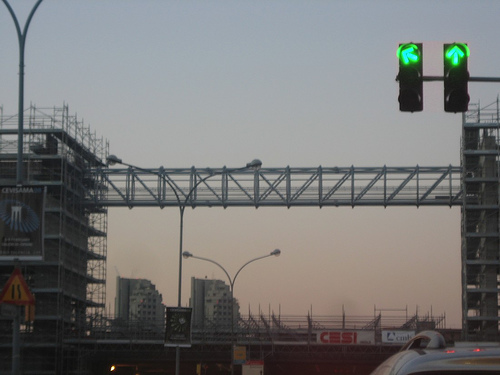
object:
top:
[397, 328, 500, 350]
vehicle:
[395, 361, 497, 374]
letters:
[319, 333, 352, 344]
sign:
[313, 328, 362, 346]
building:
[187, 275, 239, 333]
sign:
[0, 269, 37, 306]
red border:
[31, 293, 39, 302]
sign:
[162, 306, 193, 349]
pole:
[169, 272, 191, 298]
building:
[112, 276, 167, 334]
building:
[0, 101, 110, 372]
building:
[451, 94, 500, 341]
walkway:
[96, 158, 462, 210]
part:
[9, 348, 29, 358]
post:
[0, 257, 39, 356]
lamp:
[3, 0, 39, 67]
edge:
[367, 328, 379, 350]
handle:
[418, 330, 443, 350]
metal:
[52, 101, 80, 124]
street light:
[180, 248, 280, 338]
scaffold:
[65, 112, 110, 320]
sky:
[0, 0, 500, 333]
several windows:
[145, 310, 155, 318]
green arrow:
[395, 45, 424, 67]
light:
[395, 41, 425, 113]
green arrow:
[442, 43, 471, 67]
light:
[443, 42, 470, 114]